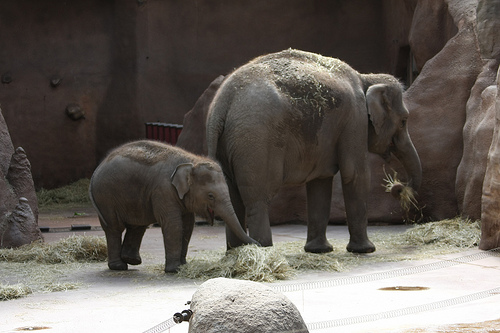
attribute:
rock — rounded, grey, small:
[184, 271, 296, 331]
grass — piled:
[270, 52, 343, 105]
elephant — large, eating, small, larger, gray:
[224, 44, 402, 151]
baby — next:
[98, 122, 230, 213]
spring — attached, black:
[167, 296, 201, 329]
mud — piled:
[363, 263, 449, 321]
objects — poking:
[28, 59, 123, 134]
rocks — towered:
[414, 6, 496, 131]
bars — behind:
[144, 116, 191, 147]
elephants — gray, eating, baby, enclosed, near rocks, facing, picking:
[98, 88, 402, 270]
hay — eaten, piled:
[390, 156, 429, 207]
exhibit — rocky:
[34, 19, 489, 244]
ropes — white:
[34, 214, 116, 247]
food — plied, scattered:
[201, 238, 292, 275]